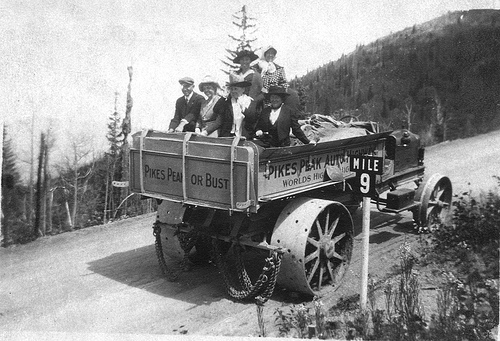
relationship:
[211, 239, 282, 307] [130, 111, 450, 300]
chain hanging off truck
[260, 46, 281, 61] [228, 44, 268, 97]
bonnet on head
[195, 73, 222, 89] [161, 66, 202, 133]
cap on man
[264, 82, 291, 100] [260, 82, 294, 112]
hat on head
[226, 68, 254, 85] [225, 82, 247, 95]
hat on head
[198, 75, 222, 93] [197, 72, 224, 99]
cap on person's head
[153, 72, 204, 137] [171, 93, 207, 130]
man wearing jacket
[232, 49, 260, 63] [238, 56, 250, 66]
bonnet on head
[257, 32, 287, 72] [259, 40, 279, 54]
head wearing bonnet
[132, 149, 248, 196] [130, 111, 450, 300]
sign written on truck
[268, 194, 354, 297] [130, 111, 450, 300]
truck wheel on back of truck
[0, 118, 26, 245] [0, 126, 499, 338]
tree in roadside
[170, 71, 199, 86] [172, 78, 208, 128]
cap in man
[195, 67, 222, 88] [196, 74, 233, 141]
white hat in woman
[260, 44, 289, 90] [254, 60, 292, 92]
person in dress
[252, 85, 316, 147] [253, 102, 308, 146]
woman in jacket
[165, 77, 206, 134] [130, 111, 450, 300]
man in back of truck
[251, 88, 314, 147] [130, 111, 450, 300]
person in back of truck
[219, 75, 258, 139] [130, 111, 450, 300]
person in back of truck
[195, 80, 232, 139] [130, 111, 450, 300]
person in back of truck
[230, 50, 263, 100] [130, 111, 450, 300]
person in back of truck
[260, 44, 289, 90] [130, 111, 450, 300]
person in back of truck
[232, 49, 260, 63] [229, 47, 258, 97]
bonnet on woman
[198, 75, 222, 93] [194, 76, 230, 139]
cap on woman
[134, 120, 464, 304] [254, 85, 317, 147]
truck carrying person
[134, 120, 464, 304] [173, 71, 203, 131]
truck carrying man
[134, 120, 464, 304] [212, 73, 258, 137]
truck carrying person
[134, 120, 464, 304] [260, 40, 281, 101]
truck carrying woman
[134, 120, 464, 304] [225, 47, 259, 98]
truck carrying woman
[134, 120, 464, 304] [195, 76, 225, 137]
truck carrying woman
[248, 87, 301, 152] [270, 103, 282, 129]
woman wearing shirt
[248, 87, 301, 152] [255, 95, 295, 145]
woman wearing jacket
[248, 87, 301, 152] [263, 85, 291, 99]
woman wearing hat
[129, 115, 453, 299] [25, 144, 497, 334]
truck on road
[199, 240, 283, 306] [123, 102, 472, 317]
chains on back of truck